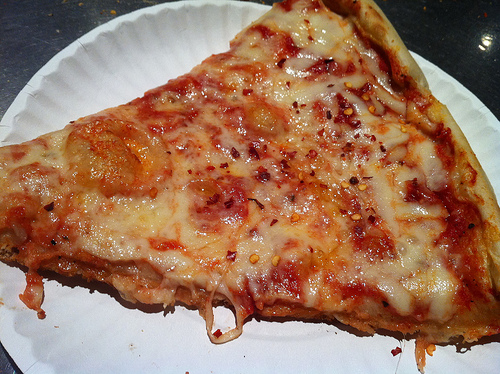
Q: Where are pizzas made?
A: At a pizzeria.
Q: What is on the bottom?
A: Crust.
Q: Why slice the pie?
A: Ease of serving.